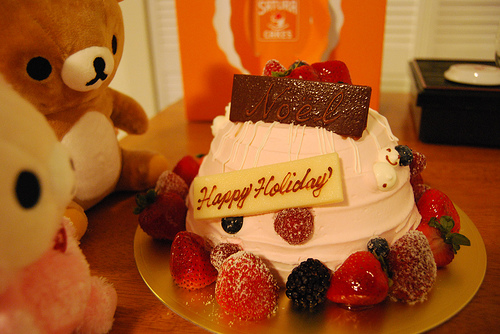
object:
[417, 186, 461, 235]
strawberry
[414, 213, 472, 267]
strawberry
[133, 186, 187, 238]
strawberry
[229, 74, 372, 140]
chocolate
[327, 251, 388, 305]
berries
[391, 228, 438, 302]
berries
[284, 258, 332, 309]
berries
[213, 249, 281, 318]
berries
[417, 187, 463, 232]
berries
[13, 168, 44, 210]
toy eye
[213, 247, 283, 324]
berry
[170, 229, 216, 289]
berry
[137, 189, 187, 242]
berry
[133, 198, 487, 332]
platter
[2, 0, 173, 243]
bear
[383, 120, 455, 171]
ground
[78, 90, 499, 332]
table top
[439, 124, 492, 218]
table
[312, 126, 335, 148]
drizzles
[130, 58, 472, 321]
cake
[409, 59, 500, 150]
wooden box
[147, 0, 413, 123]
box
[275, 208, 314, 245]
raspberry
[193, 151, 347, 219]
sign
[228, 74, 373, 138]
sign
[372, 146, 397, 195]
icing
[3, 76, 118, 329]
animal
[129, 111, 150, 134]
paw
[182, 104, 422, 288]
icing